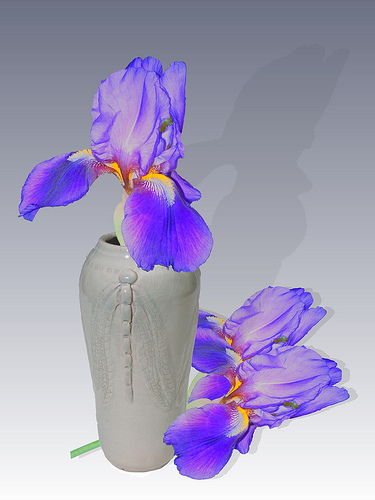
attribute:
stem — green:
[67, 438, 102, 459]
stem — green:
[68, 432, 109, 463]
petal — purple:
[118, 183, 211, 274]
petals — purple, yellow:
[172, 282, 346, 476]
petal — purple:
[116, 167, 220, 275]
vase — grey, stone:
[19, 47, 236, 340]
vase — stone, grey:
[38, 188, 275, 479]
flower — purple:
[246, 283, 310, 347]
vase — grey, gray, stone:
[82, 236, 200, 472]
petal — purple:
[113, 169, 226, 270]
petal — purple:
[80, 57, 171, 185]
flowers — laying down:
[162, 276, 333, 476]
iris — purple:
[13, 36, 220, 220]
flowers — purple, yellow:
[13, 52, 217, 274]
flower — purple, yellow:
[19, 54, 218, 274]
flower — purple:
[17, 62, 248, 275]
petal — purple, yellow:
[119, 169, 215, 272]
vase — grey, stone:
[76, 229, 212, 482]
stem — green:
[47, 430, 113, 463]